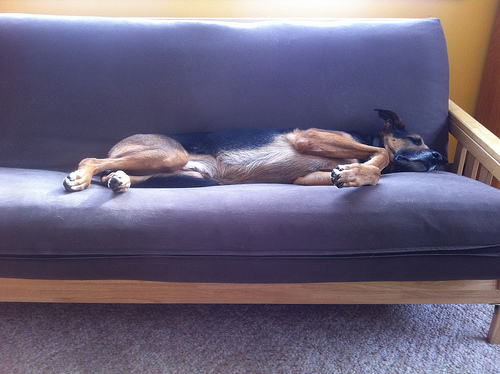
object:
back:
[0, 13, 452, 160]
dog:
[63, 106, 443, 199]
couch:
[28, 10, 473, 301]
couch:
[0, 17, 499, 344]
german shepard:
[60, 102, 449, 198]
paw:
[63, 171, 93, 191]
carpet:
[5, 292, 498, 369]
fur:
[198, 125, 259, 163]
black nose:
[425, 150, 442, 163]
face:
[389, 127, 441, 171]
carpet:
[2, 300, 498, 370]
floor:
[0, 299, 499, 372]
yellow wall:
[434, 5, 496, 104]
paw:
[104, 168, 134, 196]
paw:
[329, 164, 364, 190]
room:
[1, 0, 500, 373]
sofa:
[0, 10, 499, 347]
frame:
[1, 276, 496, 305]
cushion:
[2, 12, 498, 279]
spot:
[260, 137, 274, 149]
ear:
[373, 106, 405, 129]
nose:
[428, 148, 445, 164]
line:
[4, 240, 484, 263]